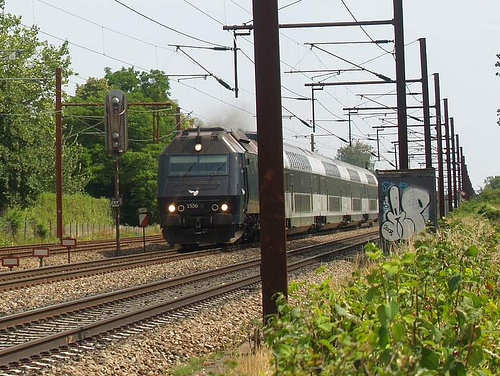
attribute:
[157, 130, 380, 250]
train — black colored, silver, black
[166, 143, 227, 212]
headlights — on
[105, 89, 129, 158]
train signal — metal, small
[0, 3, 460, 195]
power cables — here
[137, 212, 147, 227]
sign — here, red, white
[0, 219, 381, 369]
train tracks — many, here, dark, iron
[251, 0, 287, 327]
pole — wooden, iron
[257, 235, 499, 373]
plants — leafy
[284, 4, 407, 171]
electrical post — here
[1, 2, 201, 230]
forest — here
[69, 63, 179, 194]
tree — leafy, green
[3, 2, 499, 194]
sky — here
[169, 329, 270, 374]
grass — green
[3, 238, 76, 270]
signs — together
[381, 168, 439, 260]
graffiti — here, black, white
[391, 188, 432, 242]
sign — metal